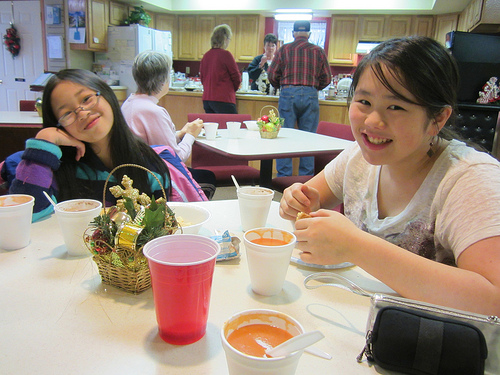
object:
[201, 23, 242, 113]
person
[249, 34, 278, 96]
person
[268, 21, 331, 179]
person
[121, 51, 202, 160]
person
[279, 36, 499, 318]
person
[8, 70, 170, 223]
person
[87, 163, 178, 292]
basket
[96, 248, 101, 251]
flowers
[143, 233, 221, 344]
cup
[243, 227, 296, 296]
cup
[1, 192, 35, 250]
cup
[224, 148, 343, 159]
edge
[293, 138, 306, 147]
part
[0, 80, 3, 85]
handle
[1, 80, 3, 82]
part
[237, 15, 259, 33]
shade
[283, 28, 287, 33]
part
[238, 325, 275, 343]
liquid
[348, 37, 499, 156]
hair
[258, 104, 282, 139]
basket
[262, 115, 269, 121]
fruit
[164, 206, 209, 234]
bowl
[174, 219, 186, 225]
ice cream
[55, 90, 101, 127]
glasses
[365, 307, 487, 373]
bag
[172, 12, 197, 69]
wall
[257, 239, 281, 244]
liquid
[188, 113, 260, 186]
chair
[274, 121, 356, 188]
chair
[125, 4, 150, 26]
plant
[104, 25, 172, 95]
refrigerator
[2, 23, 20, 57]
decor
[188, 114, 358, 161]
counter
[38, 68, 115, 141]
head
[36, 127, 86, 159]
hand